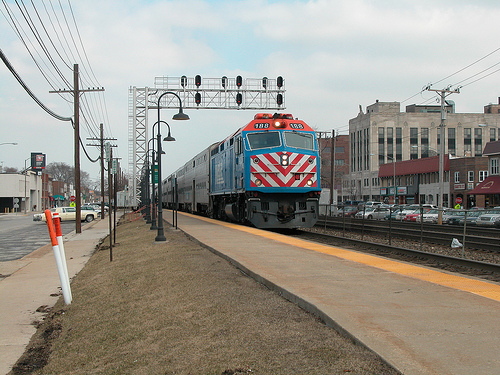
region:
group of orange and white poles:
[39, 209, 78, 315]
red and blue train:
[161, 109, 334, 229]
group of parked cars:
[323, 194, 498, 230]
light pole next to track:
[148, 110, 178, 246]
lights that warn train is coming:
[123, 84, 301, 107]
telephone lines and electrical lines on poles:
[3, 0, 123, 223]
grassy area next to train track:
[36, 232, 361, 366]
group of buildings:
[346, 102, 498, 209]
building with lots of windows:
[371, 121, 439, 156]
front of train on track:
[241, 97, 331, 235]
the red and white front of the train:
[250, 151, 320, 192]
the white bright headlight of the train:
[280, 155, 286, 160]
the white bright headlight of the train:
[281, 158, 288, 168]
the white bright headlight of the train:
[255, 178, 262, 187]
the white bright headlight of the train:
[304, 179, 313, 187]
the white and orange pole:
[42, 208, 80, 303]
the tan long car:
[25, 207, 98, 223]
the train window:
[245, 129, 282, 151]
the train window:
[285, 131, 314, 151]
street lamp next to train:
[154, 90, 185, 254]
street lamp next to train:
[151, 118, 171, 243]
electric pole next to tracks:
[55, 58, 100, 233]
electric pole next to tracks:
[87, 119, 115, 244]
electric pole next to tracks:
[430, 83, 460, 226]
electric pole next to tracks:
[318, 125, 345, 209]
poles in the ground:
[35, 202, 95, 312]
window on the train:
[246, 127, 279, 149]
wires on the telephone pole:
[6, 3, 108, 123]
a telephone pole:
[62, 70, 96, 231]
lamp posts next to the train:
[138, 85, 198, 236]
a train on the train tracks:
[173, 112, 340, 232]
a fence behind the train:
[315, 203, 499, 264]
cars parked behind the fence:
[337, 194, 494, 226]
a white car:
[33, 204, 94, 219]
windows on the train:
[249, 131, 315, 151]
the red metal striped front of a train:
[248, 151, 317, 186]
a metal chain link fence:
[327, 201, 499, 257]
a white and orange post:
[43, 209, 74, 304]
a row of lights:
[141, 83, 193, 242]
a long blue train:
[144, 109, 320, 229]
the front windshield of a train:
[247, 128, 316, 152]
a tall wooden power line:
[425, 81, 461, 217]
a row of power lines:
[54, 65, 130, 240]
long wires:
[2, 2, 125, 163]